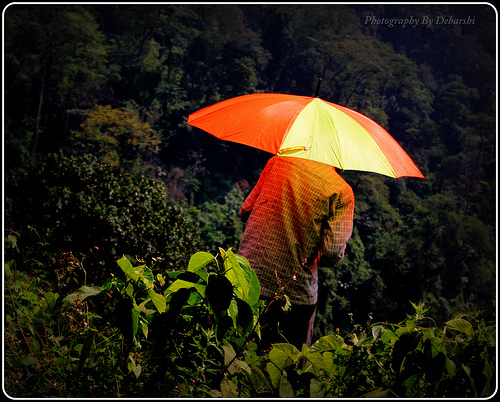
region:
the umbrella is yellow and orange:
[236, 50, 353, 261]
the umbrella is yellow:
[265, 65, 330, 202]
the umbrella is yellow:
[245, 28, 402, 344]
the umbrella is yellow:
[233, 85, 353, 217]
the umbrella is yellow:
[185, 67, 339, 317]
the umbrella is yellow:
[228, 11, 380, 226]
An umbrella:
[231, 82, 412, 259]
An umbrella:
[262, 75, 394, 182]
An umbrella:
[203, 52, 330, 198]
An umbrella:
[275, 75, 339, 250]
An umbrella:
[268, 159, 351, 389]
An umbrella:
[300, 90, 345, 183]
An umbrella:
[256, 47, 326, 167]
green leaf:
[196, 245, 298, 355]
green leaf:
[187, 238, 251, 324]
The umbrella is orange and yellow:
[178, 81, 432, 216]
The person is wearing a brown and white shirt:
[237, 137, 348, 303]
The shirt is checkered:
[220, 135, 360, 307]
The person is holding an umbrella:
[176, 83, 406, 335]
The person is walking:
[191, 83, 393, 344]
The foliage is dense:
[22, 49, 464, 379]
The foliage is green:
[43, 63, 443, 363]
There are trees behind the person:
[163, 48, 457, 211]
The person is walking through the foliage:
[196, 61, 398, 347]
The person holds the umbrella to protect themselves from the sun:
[183, 77, 422, 328]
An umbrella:
[134, 64, 496, 312]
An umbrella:
[156, 10, 464, 231]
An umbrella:
[154, 16, 358, 322]